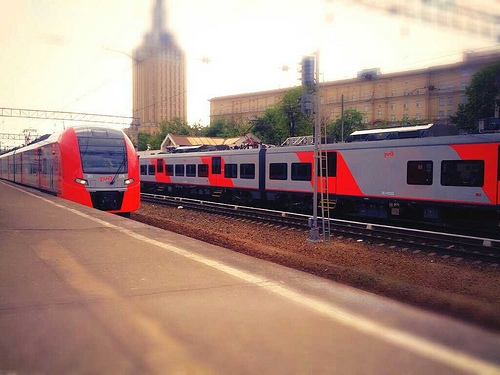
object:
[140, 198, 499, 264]
railway line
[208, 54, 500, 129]
building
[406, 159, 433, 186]
window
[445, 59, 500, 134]
tree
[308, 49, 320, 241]
pole